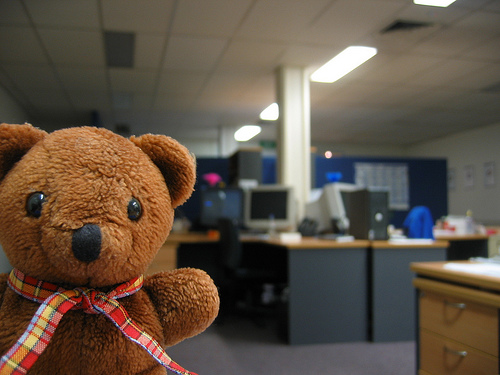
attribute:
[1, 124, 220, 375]
teddy bear — brown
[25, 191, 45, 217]
eye — black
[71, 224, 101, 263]
nose — black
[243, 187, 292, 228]
monitor — computer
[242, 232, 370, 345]
desk — brown, black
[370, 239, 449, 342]
desk — brown, black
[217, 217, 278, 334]
chair — black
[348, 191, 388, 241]
computer tower — black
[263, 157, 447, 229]
cubicle — blue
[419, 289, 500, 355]
drawer — brown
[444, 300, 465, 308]
handle — gray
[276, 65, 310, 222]
pole — white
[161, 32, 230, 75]
ceiling tile — white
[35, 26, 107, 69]
ceiling tile — white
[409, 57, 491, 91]
ceiling tile — white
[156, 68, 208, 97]
ceiling tile — white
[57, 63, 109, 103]
ceiling tile — white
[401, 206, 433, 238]
jacket — blue